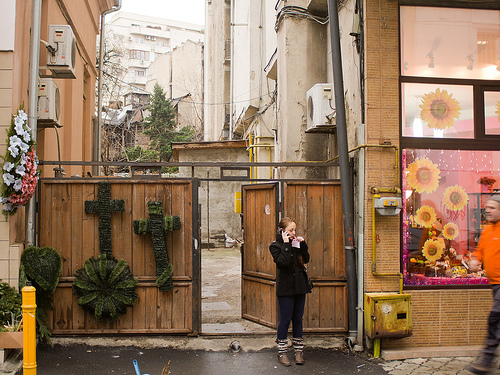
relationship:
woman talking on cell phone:
[269, 217, 314, 366] [279, 227, 292, 239]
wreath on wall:
[74, 257, 137, 319] [34, 178, 196, 336]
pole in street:
[20, 285, 40, 373] [0, 348, 499, 374]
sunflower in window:
[420, 88, 459, 130] [398, 4, 498, 291]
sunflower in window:
[407, 158, 442, 194] [398, 4, 498, 291]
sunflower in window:
[441, 185, 470, 212] [398, 4, 498, 291]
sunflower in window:
[414, 204, 436, 227] [398, 4, 498, 291]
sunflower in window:
[441, 223, 459, 240] [398, 4, 498, 291]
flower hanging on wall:
[0, 106, 40, 218] [2, 1, 37, 290]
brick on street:
[394, 360, 419, 373] [0, 348, 499, 374]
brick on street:
[420, 357, 447, 369] [0, 348, 499, 374]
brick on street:
[434, 364, 454, 374] [0, 348, 499, 374]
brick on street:
[412, 366, 432, 374] [0, 348, 499, 374]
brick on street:
[446, 358, 469, 369] [0, 348, 499, 374]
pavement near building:
[25, 346, 387, 374] [232, 2, 500, 362]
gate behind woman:
[240, 183, 280, 331] [269, 217, 314, 366]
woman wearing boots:
[269, 217, 314, 366] [275, 339, 306, 366]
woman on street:
[269, 217, 314, 366] [0, 348, 499, 374]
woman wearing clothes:
[269, 217, 314, 366] [269, 235, 312, 337]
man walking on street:
[465, 195, 499, 374] [0, 348, 499, 374]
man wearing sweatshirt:
[465, 195, 499, 374] [473, 222, 499, 283]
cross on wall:
[83, 181, 126, 256] [34, 178, 196, 336]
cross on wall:
[135, 198, 179, 293] [34, 178, 196, 336]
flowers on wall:
[0, 106, 40, 218] [2, 1, 37, 290]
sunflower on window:
[422, 239, 444, 261] [398, 4, 498, 291]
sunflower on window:
[420, 88, 459, 130] [398, 4, 498, 291]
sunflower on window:
[407, 158, 442, 194] [398, 4, 498, 291]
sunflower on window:
[441, 185, 470, 212] [398, 4, 498, 291]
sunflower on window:
[414, 204, 436, 227] [398, 4, 498, 291]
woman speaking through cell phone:
[269, 217, 314, 366] [279, 227, 292, 239]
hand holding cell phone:
[280, 231, 291, 239] [279, 227, 292, 239]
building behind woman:
[232, 2, 500, 362] [269, 217, 314, 366]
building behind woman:
[2, 0, 121, 293] [269, 217, 314, 366]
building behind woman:
[144, 38, 207, 175] [269, 217, 314, 366]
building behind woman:
[99, 10, 209, 122] [269, 217, 314, 366]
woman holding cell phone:
[269, 217, 314, 366] [279, 227, 292, 239]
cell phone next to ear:
[279, 227, 292, 239] [277, 228, 283, 236]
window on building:
[398, 4, 498, 291] [232, 2, 500, 362]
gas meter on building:
[365, 291, 414, 338] [232, 2, 500, 362]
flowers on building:
[0, 106, 40, 218] [2, 0, 121, 293]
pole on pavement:
[20, 285, 40, 373] [25, 346, 387, 374]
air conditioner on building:
[48, 23, 78, 79] [2, 0, 121, 293]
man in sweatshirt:
[465, 195, 499, 374] [473, 222, 499, 283]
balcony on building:
[129, 26, 168, 41] [99, 10, 209, 122]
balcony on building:
[124, 76, 147, 87] [99, 10, 209, 122]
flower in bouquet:
[15, 123, 24, 136] [0, 106, 40, 218]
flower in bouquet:
[18, 109, 29, 121] [0, 106, 40, 218]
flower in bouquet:
[14, 179, 24, 191] [0, 106, 40, 218]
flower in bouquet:
[3, 170, 17, 186] [0, 106, 40, 218]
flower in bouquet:
[10, 135, 22, 145] [0, 106, 40, 218]